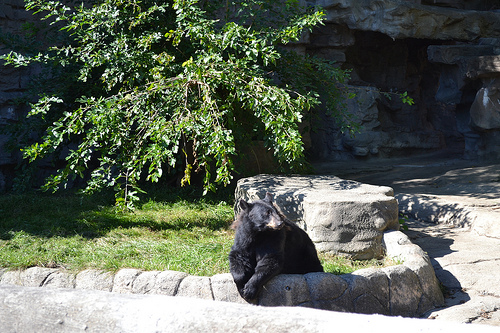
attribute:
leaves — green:
[0, 3, 327, 216]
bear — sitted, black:
[222, 189, 329, 310]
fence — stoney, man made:
[0, 262, 450, 312]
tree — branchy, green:
[0, 2, 333, 197]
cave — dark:
[340, 28, 453, 145]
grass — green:
[6, 201, 231, 266]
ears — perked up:
[232, 188, 281, 217]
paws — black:
[232, 278, 270, 307]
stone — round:
[289, 168, 404, 258]